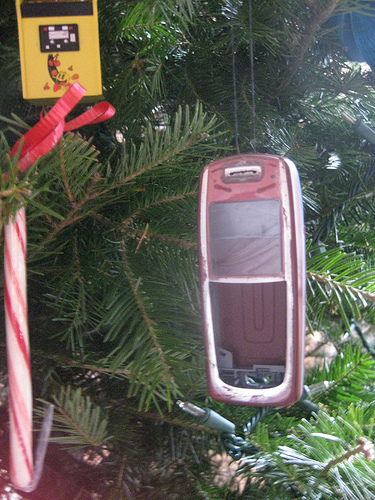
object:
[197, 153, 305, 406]
phone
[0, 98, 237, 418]
tree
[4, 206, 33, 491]
candy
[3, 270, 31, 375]
red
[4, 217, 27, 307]
white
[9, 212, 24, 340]
cane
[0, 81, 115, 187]
ribbon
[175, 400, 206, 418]
white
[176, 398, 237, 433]
light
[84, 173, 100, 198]
pine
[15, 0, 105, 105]
decorations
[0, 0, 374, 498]
scene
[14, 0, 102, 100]
yellow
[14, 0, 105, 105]
object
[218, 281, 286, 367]
broken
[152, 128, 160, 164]
needles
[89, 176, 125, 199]
branches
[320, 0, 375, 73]
ornament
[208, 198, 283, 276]
clear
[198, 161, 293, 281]
screen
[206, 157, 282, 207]
piece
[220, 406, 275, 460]
cord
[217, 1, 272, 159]
strands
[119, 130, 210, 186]
twig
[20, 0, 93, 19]
black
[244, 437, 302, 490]
wires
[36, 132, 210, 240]
limb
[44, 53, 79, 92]
pac-man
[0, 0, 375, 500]
evergreen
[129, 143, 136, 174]
leaflets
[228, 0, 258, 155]
rope